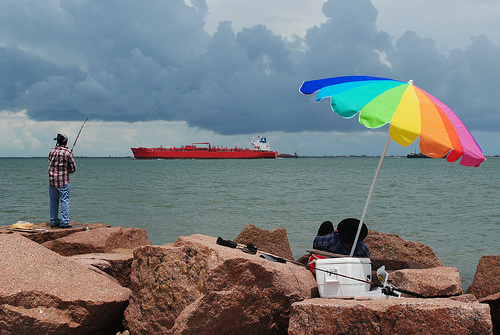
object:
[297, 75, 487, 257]
umbrella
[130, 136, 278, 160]
ship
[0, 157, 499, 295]
water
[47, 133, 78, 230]
man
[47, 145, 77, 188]
shirt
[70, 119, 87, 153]
pole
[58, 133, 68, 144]
bandana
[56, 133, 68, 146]
head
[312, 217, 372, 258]
man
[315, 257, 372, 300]
cooler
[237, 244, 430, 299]
pole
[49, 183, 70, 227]
jeans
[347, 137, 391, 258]
pole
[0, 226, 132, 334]
rocks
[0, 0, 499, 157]
sky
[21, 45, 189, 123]
clouds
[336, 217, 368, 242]
cap